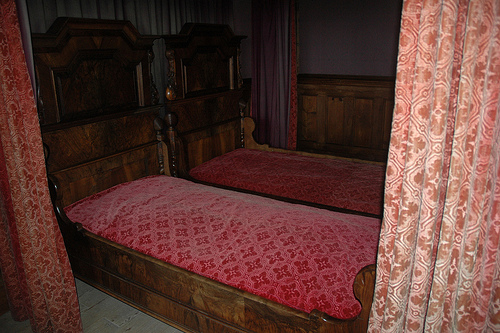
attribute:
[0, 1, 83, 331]
fabric — red, ornate, hanging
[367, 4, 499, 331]
fabric — red, ornate, hanging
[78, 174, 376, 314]
fabric — red, ornate, hanging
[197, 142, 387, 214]
fabric — red, ornate, hanging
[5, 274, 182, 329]
floor — part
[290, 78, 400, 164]
cupboard — brown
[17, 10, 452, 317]
scene — inside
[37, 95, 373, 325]
bed frame — wooden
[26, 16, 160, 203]
headboard — wooden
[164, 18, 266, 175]
headboard — wooden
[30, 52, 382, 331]
bed — wooden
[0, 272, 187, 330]
tile floor — white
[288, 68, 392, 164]
cupboard — wooden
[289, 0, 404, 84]
wall — white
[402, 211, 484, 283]
curtain — part